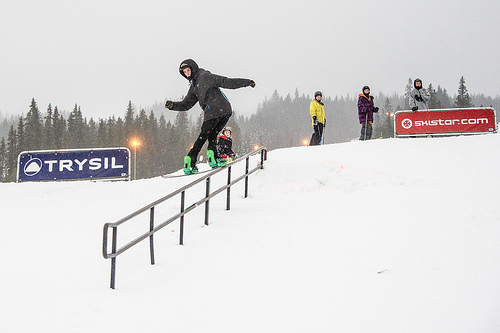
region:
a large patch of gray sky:
[0, 0, 499, 125]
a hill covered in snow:
[0, 128, 499, 331]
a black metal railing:
[102, 145, 267, 287]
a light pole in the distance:
[131, 140, 140, 180]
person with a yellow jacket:
[308, 90, 326, 145]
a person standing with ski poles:
[356, 85, 378, 140]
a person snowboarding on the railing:
[164, 58, 256, 178]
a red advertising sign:
[393, 106, 496, 138]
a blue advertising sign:
[15, 146, 130, 182]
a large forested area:
[0, 75, 499, 182]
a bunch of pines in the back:
[0, 79, 491, 176]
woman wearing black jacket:
[154, 61, 258, 171]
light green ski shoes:
[182, 150, 229, 173]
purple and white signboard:
[15, 147, 132, 180]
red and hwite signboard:
[389, 107, 498, 136]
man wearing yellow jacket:
[307, 90, 328, 142]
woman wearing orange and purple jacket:
[357, 83, 379, 135]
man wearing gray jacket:
[409, 77, 429, 115]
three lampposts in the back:
[124, 135, 311, 175]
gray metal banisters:
[100, 144, 267, 290]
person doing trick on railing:
[173, 45, 244, 168]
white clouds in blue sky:
[340, 15, 374, 57]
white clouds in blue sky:
[303, 13, 363, 78]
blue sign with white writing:
[10, 126, 139, 202]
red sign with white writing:
[375, 105, 497, 152]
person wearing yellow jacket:
[302, 93, 331, 126]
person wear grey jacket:
[155, 48, 260, 123]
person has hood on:
[171, 51, 204, 83]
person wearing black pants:
[185, 106, 237, 161]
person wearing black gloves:
[161, 77, 258, 113]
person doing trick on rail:
[154, 53, 265, 220]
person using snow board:
[154, 45, 253, 212]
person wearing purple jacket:
[352, 90, 379, 126]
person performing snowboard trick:
[120, 50, 277, 177]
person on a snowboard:
[125, 45, 265, 180]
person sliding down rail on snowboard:
[84, 35, 274, 220]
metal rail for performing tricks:
[53, 141, 304, 298]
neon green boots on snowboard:
[171, 146, 243, 181]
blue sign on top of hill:
[2, 133, 132, 184]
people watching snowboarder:
[284, 37, 436, 147]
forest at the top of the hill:
[7, 67, 493, 155]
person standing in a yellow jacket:
[289, 79, 338, 151]